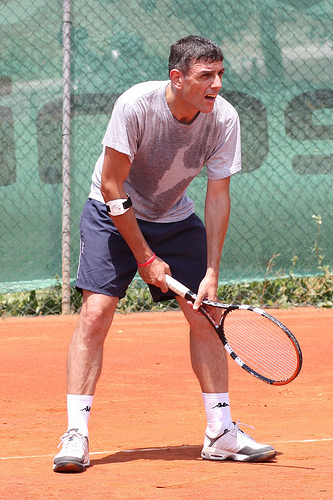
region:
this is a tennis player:
[34, 29, 244, 462]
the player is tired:
[50, 25, 269, 489]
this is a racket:
[162, 267, 292, 377]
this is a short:
[77, 224, 116, 285]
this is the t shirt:
[138, 127, 201, 201]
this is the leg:
[70, 345, 95, 377]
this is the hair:
[176, 34, 211, 56]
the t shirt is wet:
[137, 128, 203, 191]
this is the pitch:
[118, 342, 186, 431]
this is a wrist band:
[136, 253, 158, 269]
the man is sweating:
[121, 36, 218, 260]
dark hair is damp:
[67, 6, 295, 346]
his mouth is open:
[74, 15, 259, 352]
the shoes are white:
[48, 369, 86, 470]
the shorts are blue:
[67, 143, 211, 353]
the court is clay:
[95, 385, 269, 481]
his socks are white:
[176, 340, 280, 494]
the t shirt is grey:
[59, 26, 254, 242]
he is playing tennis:
[69, 36, 255, 498]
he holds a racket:
[63, 23, 308, 467]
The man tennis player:
[48, 35, 324, 472]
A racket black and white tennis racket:
[164, 272, 301, 385]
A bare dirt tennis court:
[0, 308, 332, 498]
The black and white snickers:
[49, 428, 273, 475]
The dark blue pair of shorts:
[76, 196, 207, 302]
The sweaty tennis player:
[53, 36, 276, 472]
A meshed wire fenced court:
[0, 0, 332, 315]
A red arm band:
[135, 254, 157, 267]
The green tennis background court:
[0, 0, 332, 294]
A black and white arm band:
[103, 193, 137, 215]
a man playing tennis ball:
[89, 101, 275, 368]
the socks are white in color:
[208, 385, 230, 432]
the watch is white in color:
[108, 204, 121, 212]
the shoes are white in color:
[216, 431, 265, 462]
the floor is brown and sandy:
[181, 465, 256, 497]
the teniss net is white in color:
[219, 304, 281, 376]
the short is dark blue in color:
[76, 215, 199, 277]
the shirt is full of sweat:
[143, 103, 219, 221]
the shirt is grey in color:
[141, 114, 209, 215]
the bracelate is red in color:
[135, 254, 153, 265]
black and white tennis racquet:
[165, 274, 302, 386]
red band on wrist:
[136, 252, 156, 269]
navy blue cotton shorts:
[75, 197, 210, 302]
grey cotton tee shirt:
[84, 79, 243, 225]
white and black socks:
[64, 394, 234, 433]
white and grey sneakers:
[54, 431, 275, 461]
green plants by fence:
[0, 278, 332, 314]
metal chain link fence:
[2, 0, 332, 282]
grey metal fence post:
[62, 0, 71, 317]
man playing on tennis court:
[53, 34, 277, 469]